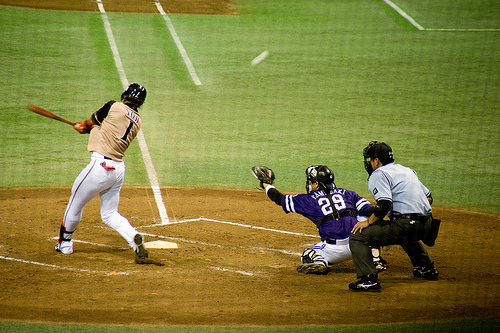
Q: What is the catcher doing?
A: Waiting for the ball.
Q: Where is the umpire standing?
A: Behind catcher.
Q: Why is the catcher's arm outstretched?
A: Catching ball.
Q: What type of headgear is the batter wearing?
A: Helmet.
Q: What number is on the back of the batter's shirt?
A: 1.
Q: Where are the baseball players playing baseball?
A: Baseball field.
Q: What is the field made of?
A: Grass.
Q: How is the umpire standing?
A: Crouching.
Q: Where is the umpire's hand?
A: Knee.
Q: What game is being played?
A: Baseball.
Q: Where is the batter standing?
A: Batters box.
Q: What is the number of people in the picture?
A: 3.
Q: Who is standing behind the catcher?
A: Umpire.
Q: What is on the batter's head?
A: Helmet.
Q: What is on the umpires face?
A: Mask.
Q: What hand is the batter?
A: Right.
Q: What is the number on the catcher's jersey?
A: 29.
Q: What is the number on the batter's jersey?
A: 1.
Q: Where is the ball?
A: Air.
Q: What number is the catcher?
A: 29.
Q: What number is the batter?
A: 1.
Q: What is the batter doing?
A: Swinging.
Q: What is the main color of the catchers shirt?
A: Purple.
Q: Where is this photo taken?
A: Baseball field.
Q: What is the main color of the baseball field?
A: Green.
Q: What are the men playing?
A: Baseball.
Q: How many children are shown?
A: Zero.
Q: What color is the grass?
A: Green.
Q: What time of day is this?
A: Daytime.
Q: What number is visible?
A: 29.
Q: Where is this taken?
A: Baseball field.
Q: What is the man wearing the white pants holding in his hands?
A: Baseball bat.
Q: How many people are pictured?
A: Three.